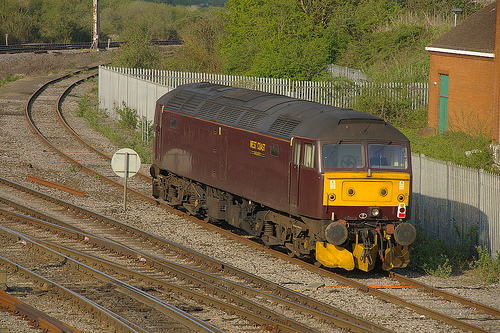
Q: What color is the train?
A: Burgundy and yellow.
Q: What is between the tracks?
A: Gravel.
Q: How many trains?
A: One.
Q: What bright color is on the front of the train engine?
A: Yellow.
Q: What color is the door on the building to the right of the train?
A: Green.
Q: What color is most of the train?
A: Brown.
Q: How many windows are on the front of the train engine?
A: Two.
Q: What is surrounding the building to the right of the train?
A: Fence.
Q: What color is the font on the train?
A: Yellow.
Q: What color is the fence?
A: Gray.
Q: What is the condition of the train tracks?
A: Rusted.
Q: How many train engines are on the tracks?
A: One.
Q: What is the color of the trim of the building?
A: White.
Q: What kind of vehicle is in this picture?
A: A Train.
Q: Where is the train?
A: On the tracks.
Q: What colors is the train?
A: Burgundy and Yellow.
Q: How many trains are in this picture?
A: One.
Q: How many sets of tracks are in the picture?
A: Four.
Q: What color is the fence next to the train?
A: White.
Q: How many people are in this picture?
A: Zero.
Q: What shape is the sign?
A: A circle.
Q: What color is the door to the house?
A: Green.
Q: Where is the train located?
A: On tracks.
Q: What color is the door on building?
A: Green.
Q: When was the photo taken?
A: Daytime.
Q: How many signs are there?
A: One.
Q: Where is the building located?
A: To the right of train.